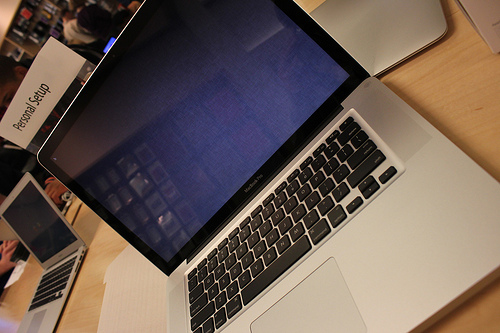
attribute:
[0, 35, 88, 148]
sign — white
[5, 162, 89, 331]
laptop — open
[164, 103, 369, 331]
keyboard — black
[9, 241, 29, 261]
object — black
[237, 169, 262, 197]
letters — silver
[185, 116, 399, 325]
keyboard — black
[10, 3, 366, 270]
screen — blue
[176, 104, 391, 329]
keyboard — black 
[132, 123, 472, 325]
keyboard — black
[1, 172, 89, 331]
apple — Apple 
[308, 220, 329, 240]
key — black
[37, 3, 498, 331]
apple-macbook pro — Apple 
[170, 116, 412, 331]
keyboard — black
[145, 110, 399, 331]
keypad — black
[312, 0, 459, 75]
panel — curved, metal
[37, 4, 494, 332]
laptop — open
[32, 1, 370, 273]
frame — black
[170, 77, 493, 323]
case — gray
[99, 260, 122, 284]
corner — tabbed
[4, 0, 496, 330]
surface — flat, wooden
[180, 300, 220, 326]
key — shift 